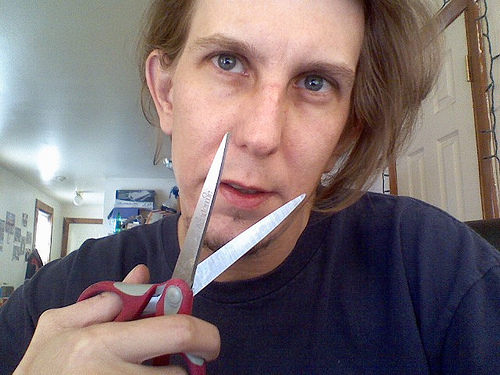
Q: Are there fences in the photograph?
A: No, there are no fences.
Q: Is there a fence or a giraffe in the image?
A: No, there are no fences or giraffes.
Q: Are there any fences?
A: No, there are no fences.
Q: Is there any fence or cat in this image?
A: No, there are no fences or cats.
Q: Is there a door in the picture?
A: Yes, there is a door.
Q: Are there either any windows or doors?
A: Yes, there is a door.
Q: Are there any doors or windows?
A: Yes, there is a door.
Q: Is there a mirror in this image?
A: No, there are no mirrors.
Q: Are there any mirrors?
A: No, there are no mirrors.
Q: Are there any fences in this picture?
A: No, there are no fences.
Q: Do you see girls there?
A: No, there are no girls.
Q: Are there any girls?
A: No, there are no girls.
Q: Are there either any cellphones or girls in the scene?
A: No, there are no girls or cellphones.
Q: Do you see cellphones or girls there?
A: No, there are no girls or cellphones.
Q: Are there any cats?
A: No, there are no cats.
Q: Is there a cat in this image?
A: No, there are no cats.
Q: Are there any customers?
A: No, there are no customers.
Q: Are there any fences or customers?
A: No, there are no customers or fences.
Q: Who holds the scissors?
A: The man holds the scissors.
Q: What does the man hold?
A: The man holds the scissors.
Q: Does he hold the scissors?
A: Yes, the man holds the scissors.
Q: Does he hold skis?
A: No, the man holds the scissors.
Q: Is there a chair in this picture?
A: No, there are no chairs.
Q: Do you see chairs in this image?
A: No, there are no chairs.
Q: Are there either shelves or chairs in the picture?
A: No, there are no chairs or shelves.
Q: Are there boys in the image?
A: No, there are no boys.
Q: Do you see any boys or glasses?
A: No, there are no boys or glasses.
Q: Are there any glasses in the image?
A: No, there are no glasses.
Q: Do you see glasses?
A: No, there are no glasses.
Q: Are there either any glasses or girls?
A: No, there are no glasses or girls.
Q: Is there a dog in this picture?
A: No, there are no dogs.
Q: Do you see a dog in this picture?
A: No, there are no dogs.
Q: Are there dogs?
A: No, there are no dogs.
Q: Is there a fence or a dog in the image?
A: No, there are no dogs or fences.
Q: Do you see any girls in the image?
A: No, there are no girls.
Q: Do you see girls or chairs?
A: No, there are no girls or chairs.